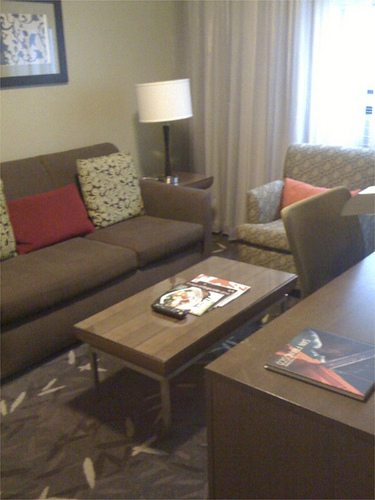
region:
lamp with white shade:
[122, 70, 212, 188]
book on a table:
[253, 312, 373, 399]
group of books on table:
[146, 267, 247, 323]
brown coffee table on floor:
[60, 244, 309, 433]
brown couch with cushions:
[0, 133, 224, 384]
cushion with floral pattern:
[69, 142, 150, 235]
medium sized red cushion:
[5, 181, 86, 259]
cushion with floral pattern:
[0, 172, 24, 264]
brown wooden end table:
[131, 150, 233, 223]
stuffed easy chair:
[216, 117, 373, 299]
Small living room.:
[9, 4, 366, 353]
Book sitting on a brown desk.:
[253, 318, 373, 407]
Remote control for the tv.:
[143, 297, 216, 331]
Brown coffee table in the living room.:
[58, 248, 308, 422]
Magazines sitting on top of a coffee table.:
[158, 267, 256, 315]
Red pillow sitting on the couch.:
[1, 178, 104, 262]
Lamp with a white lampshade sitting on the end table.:
[126, 75, 202, 199]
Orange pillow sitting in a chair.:
[276, 170, 372, 231]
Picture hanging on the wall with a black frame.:
[3, 1, 75, 88]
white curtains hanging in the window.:
[176, 3, 318, 233]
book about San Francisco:
[278, 319, 373, 399]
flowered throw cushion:
[75, 154, 150, 219]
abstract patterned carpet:
[6, 387, 149, 479]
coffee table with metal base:
[69, 308, 195, 425]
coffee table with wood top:
[61, 248, 260, 418]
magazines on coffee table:
[144, 264, 245, 335]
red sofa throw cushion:
[1, 181, 87, 254]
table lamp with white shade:
[133, 69, 194, 189]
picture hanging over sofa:
[1, 1, 71, 87]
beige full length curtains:
[180, 0, 315, 242]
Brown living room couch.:
[0, 146, 222, 342]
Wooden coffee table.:
[75, 241, 302, 404]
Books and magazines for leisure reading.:
[160, 257, 250, 322]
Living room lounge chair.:
[237, 131, 374, 293]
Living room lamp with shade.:
[118, 64, 218, 200]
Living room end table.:
[136, 151, 226, 232]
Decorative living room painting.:
[3, 1, 78, 108]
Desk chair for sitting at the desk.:
[278, 177, 369, 295]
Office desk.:
[181, 246, 372, 458]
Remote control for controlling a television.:
[142, 290, 200, 336]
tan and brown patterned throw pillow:
[72, 139, 147, 225]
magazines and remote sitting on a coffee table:
[146, 272, 248, 330]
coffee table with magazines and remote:
[91, 270, 271, 406]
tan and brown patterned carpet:
[1, 397, 186, 482]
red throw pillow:
[5, 171, 108, 249]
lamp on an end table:
[117, 57, 215, 213]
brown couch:
[7, 133, 199, 321]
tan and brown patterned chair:
[237, 126, 366, 293]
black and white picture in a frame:
[1, 4, 85, 85]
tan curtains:
[162, 10, 322, 235]